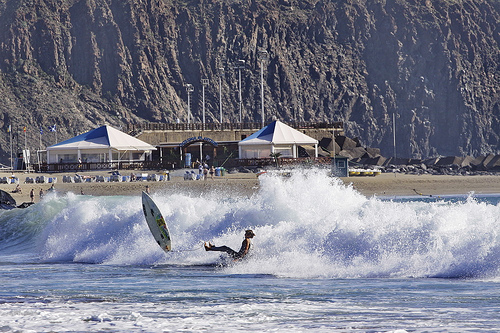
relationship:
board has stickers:
[131, 182, 181, 257] [155, 215, 162, 224]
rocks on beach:
[388, 168, 497, 178] [389, 170, 474, 201]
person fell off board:
[200, 214, 276, 281] [114, 169, 214, 285]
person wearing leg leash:
[204, 230, 255, 259] [166, 243, 203, 252]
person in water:
[204, 230, 255, 259] [3, 193, 498, 331]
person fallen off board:
[204, 230, 255, 259] [141, 192, 170, 254]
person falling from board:
[204, 230, 255, 259] [139, 190, 170, 255]